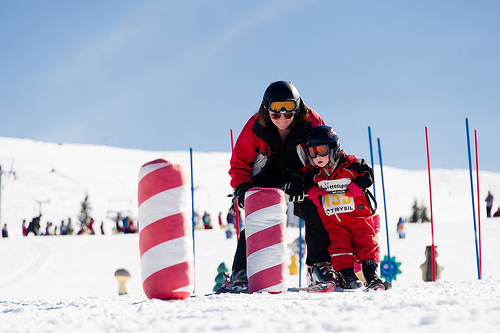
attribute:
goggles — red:
[307, 142, 328, 156]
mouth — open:
[315, 154, 329, 169]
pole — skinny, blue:
[359, 133, 391, 277]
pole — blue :
[373, 137, 399, 282]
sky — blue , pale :
[21, 10, 492, 140]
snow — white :
[2, 137, 497, 331]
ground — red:
[52, 232, 110, 317]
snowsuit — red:
[316, 168, 380, 263]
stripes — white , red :
[108, 151, 236, 318]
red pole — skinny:
[415, 135, 452, 287]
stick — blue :
[458, 114, 483, 279]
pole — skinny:
[421, 123, 439, 281]